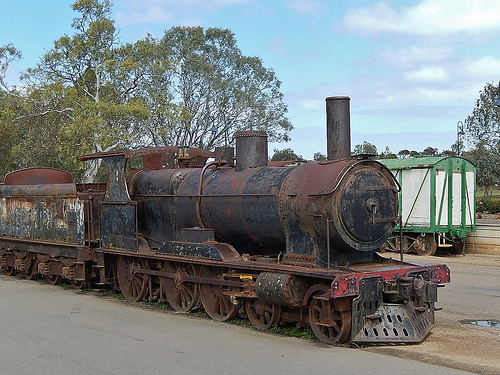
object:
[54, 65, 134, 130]
tree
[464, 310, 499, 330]
puddle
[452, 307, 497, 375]
ground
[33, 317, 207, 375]
road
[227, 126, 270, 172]
chute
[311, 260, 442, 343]
grill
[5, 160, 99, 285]
car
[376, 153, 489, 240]
train car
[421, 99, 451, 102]
cloud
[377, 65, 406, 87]
sky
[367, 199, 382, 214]
knob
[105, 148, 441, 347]
engine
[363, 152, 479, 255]
carriage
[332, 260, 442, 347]
guard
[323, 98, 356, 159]
exhausts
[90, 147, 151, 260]
cabin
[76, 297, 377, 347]
grass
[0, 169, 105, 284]
wagon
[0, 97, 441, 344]
train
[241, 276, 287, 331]
wheel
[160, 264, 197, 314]
wheel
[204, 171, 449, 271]
train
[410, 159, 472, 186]
green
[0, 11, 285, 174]
tree